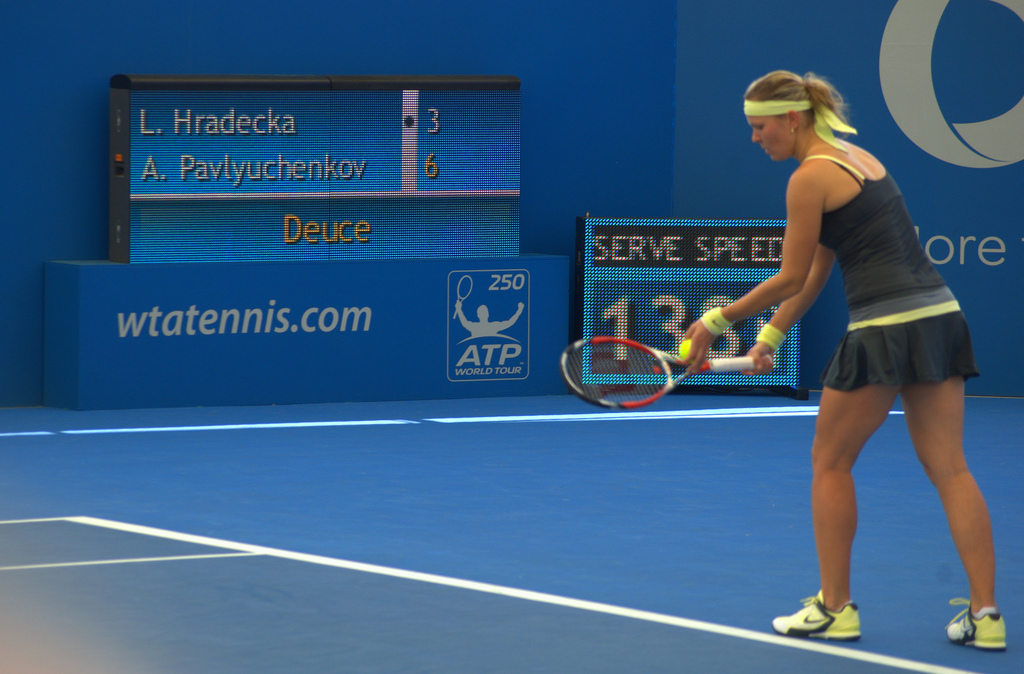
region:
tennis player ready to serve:
[545, 51, 1021, 668]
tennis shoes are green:
[764, 581, 1017, 659]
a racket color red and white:
[542, 316, 789, 421]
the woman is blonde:
[717, 43, 918, 250]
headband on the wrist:
[747, 316, 796, 361]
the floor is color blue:
[11, 391, 1021, 671]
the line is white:
[44, 499, 759, 651]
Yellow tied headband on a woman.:
[746, 92, 860, 154]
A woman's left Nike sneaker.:
[773, 590, 862, 641]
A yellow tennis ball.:
[678, 337, 692, 360]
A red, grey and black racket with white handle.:
[561, 334, 776, 408]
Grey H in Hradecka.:
[171, 105, 194, 138]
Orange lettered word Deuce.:
[282, 212, 374, 248]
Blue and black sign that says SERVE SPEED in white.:
[580, 212, 799, 387]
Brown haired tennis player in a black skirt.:
[678, 74, 1004, 650]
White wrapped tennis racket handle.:
[709, 352, 754, 373]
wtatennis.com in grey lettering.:
[115, 301, 373, 336]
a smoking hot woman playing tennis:
[694, 68, 1008, 653]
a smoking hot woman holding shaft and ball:
[566, 60, 1004, 656]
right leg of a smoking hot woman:
[901, 370, 1009, 650]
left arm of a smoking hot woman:
[680, 178, 817, 369]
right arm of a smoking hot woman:
[750, 237, 824, 370]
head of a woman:
[682, 41, 892, 185]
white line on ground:
[329, 511, 633, 666]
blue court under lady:
[433, 427, 746, 546]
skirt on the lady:
[774, 263, 990, 463]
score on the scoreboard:
[82, 79, 495, 267]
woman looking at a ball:
[474, 76, 936, 653]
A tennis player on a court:
[694, 67, 1007, 646]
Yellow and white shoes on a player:
[775, 588, 1001, 652]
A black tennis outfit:
[825, 173, 975, 388]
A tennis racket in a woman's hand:
[560, 333, 761, 404]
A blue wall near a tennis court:
[49, 256, 565, 397]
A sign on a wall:
[105, 76, 526, 255]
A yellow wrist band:
[757, 329, 787, 349]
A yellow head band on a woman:
[741, 94, 847, 155]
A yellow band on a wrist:
[696, 304, 736, 339]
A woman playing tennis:
[543, 84, 1016, 654]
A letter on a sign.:
[283, 212, 306, 245]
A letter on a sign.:
[341, 304, 383, 343]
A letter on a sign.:
[319, 304, 339, 339]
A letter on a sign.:
[300, 299, 327, 338]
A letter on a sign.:
[272, 304, 298, 331]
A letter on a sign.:
[261, 298, 285, 344]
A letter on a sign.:
[240, 299, 263, 331]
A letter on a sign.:
[215, 307, 248, 331]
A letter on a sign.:
[196, 305, 219, 332]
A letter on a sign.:
[180, 304, 200, 342]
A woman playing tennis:
[551, 55, 1020, 657]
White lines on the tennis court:
[1, 498, 988, 664]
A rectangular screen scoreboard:
[95, 59, 535, 271]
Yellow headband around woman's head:
[724, 57, 867, 172]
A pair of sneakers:
[756, 579, 1009, 657]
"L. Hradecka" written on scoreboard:
[122, 87, 306, 145]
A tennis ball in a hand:
[662, 307, 723, 383]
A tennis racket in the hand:
[548, 324, 783, 420]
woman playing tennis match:
[669, 57, 1009, 671]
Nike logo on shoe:
[802, 612, 829, 633]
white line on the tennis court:
[183, 476, 656, 672]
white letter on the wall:
[111, 315, 157, 353]